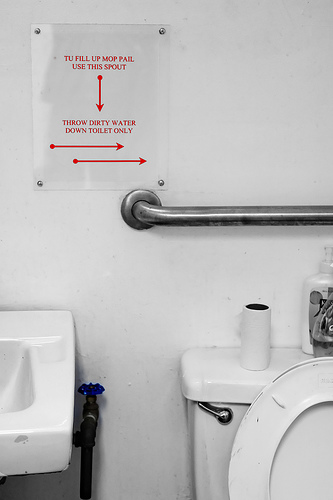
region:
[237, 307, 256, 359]
Toilet paper roll on top of the toilet.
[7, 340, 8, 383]
Toilet paper roll on top of the toilet.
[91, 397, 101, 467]
Toilet paper roll on top of the toilet.Toilet paper roll on top of the toilet.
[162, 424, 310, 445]
Toilet paper roll on top of the toilet.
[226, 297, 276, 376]
a finished roll of toilet paper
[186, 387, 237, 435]
a silver colored toilet flusher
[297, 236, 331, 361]
a soap bottle with a pump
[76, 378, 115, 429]
a blue handle for the water faucet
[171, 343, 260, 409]
the lid to the toilet tank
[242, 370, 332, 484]
the toilet seat that was left up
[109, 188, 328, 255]
a safety bar that is silver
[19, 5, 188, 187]
a set of instructions written in red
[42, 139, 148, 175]
arrows pointed to the right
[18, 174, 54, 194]
a bolt that is holding up a sign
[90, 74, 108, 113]
the arrow is pointing downward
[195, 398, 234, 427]
the handle is silver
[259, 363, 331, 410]
the lid is up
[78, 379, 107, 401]
the handle is blue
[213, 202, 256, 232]
the handle on the wall is silver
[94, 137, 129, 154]
the arrow is pointing to the right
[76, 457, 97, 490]
the pipe is black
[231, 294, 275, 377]
the paper is on the towlet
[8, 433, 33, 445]
the paint is chipping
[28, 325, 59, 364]
the sink is white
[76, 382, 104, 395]
blue plumbing handle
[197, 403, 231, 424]
toilet flush pull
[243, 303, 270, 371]
small toilet paper roll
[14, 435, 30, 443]
paint chip on the sink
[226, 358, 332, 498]
toilet seat and lid are up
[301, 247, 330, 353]
a bottle of lotion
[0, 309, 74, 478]
sink attached to the wall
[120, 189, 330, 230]
metal hand rail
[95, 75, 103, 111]
red arrow is pointing down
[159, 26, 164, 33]
metal screw on the sign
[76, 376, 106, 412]
a blue knob installed on a water faucet.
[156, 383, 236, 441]
a silver handle on a toilet.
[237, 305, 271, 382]
roll of toilet paper sitting on toilet.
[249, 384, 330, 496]
seat of a toilet lifted up.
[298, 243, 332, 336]
soap dispenser sitting on a toilet.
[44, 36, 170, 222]
signage hanging on a wall.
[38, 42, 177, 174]
red letters displayed on a sign.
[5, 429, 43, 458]
paint chipped from a sink.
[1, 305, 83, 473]
A sink hanging from a wall.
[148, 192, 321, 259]
silver railing installed above the toilet.